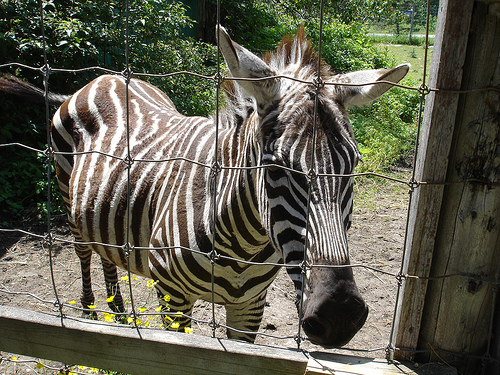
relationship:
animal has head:
[0, 22, 412, 348] [211, 17, 412, 351]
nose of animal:
[295, 287, 370, 349] [0, 22, 412, 348]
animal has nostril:
[0, 22, 412, 348] [301, 311, 326, 344]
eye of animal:
[261, 154, 284, 173] [42, 20, 415, 348]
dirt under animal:
[6, 198, 408, 350] [42, 20, 415, 348]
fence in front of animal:
[0, 0, 498, 374] [42, 20, 415, 348]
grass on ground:
[389, 43, 438, 83] [366, 25, 431, 81]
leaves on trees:
[50, 12, 183, 79] [31, 10, 176, 71]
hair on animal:
[228, 30, 359, 99] [0, 22, 412, 348]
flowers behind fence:
[10, 234, 256, 372] [0, 0, 498, 374]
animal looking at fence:
[0, 22, 412, 348] [13, 12, 493, 344]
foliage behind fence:
[163, 16, 427, 61] [0, 0, 498, 374]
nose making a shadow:
[295, 287, 370, 349] [291, 334, 385, 374]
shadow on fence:
[291, 334, 385, 374] [2, 3, 498, 370]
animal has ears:
[0, 22, 412, 348] [172, 15, 450, 139]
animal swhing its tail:
[0, 22, 412, 348] [0, 55, 115, 153]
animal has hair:
[0, 22, 412, 348] [218, 21, 336, 99]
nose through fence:
[295, 287, 370, 349] [34, 12, 457, 352]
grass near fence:
[14, 160, 390, 357] [0, 0, 498, 374]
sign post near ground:
[388, 0, 439, 67] [366, 32, 438, 54]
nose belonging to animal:
[299, 287, 372, 348] [0, 22, 412, 348]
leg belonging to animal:
[150, 277, 194, 332] [0, 22, 412, 348]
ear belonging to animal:
[209, 22, 280, 100] [0, 22, 412, 348]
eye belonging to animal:
[260, 155, 284, 173] [0, 22, 412, 348]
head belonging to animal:
[251, 76, 369, 349] [0, 22, 412, 348]